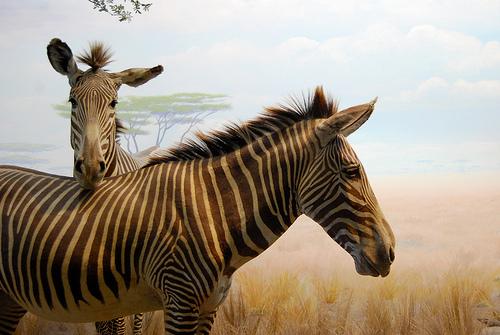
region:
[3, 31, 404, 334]
Two zebras in the wild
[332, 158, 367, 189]
Small black zebra eye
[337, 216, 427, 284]
White muzzle on zebra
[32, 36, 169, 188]
zebra looking at the camera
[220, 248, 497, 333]
Tall yellow grass in the wild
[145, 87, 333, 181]
Black and white mane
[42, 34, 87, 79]
One small white zebra ear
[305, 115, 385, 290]
Black stripes on zebra face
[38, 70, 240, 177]
Tall tree in the distance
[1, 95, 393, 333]
a striped black and white zebra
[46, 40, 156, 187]
a zebra facing forwards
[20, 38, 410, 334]
a zebra leaning on another zebra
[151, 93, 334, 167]
a zebras black mane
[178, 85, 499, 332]
a zebra in a golden field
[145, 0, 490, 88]
a bright blue sky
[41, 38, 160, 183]
a zebra with a spike of hair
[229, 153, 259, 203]
black stripe on zebra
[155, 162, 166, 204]
black stripe on zebra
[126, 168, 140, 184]
black stripe on zebra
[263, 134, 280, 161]
black stripe on zebra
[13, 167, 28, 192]
black stripe on zebra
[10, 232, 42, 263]
black stripe on zebra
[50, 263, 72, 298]
black stripe on zebra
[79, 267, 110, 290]
black stripe on zebra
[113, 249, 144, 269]
black stripe on zebra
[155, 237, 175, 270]
black stripe on zebra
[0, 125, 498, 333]
a full grown adult zebra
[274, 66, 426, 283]
the head of an adult zebra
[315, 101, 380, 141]
the ears of an adult zebra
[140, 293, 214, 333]
the front legs of an adult zebra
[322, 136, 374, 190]
the eyes of an adult zebra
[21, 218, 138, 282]
the striped pattern of a zebra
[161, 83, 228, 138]
an african tree in the distance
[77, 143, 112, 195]
the nose of an adult zebra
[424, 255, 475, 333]
a sprout of wild dry grass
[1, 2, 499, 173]
A blue sky with white clouds.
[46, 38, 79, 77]
The highest ear of a zebra.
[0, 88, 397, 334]
Horizontal standing black and white zebra.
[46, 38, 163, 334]
Vertical standing zebra with high ear.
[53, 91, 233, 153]
A distant tall tree.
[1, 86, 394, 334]
Largest black and white zebra.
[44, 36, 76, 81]
Largest black and white zebra ear.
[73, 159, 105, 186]
Nose of a zebra with two black nostrils.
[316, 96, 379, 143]
Two zebra ears pointing to the right.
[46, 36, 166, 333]
A taller black and white zebra.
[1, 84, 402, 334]
large brown and tan striped zebra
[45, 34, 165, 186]
tan and brown zebra staring straight ahead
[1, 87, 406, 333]
zebra with black mane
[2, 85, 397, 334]
large zebra facing toward the right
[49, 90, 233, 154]
tall tree with green leaves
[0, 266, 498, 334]
tall golden and brown grass in field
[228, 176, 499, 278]
large pasture behind the zebras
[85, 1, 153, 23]
small green leaves on a tree branch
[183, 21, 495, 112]
white clouds in light blue sky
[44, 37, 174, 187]
zebra looking over zebra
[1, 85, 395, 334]
zebra looking to the side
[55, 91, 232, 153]
tree behind zebras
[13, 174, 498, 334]
brown wheat behind zebras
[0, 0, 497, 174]
cloudy sky behind zebras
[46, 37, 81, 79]
right ear of zebra looking forward